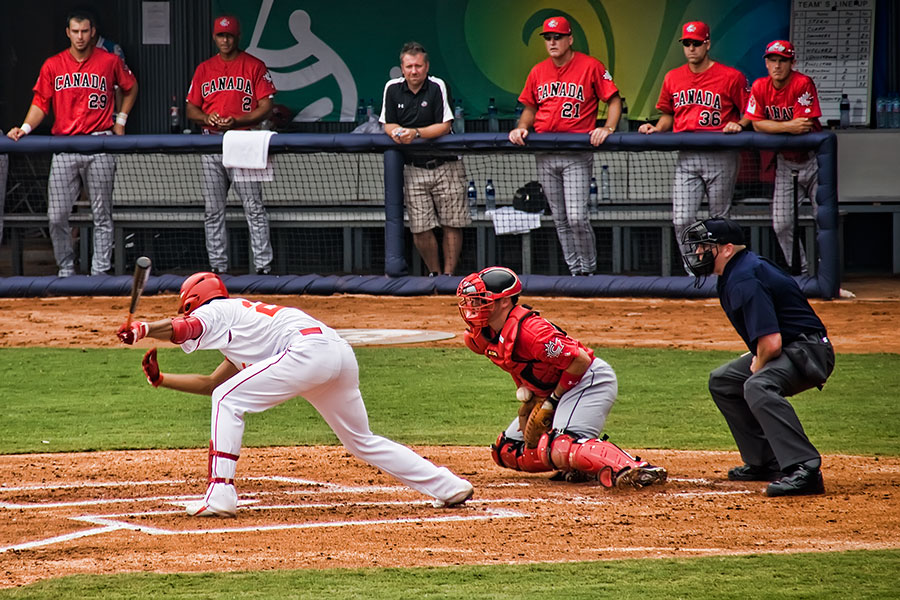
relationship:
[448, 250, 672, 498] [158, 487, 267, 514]
catcher behind home plate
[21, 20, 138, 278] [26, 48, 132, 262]
man in uniform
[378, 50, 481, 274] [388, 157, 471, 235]
man in shorts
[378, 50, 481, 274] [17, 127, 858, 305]
man in dug out